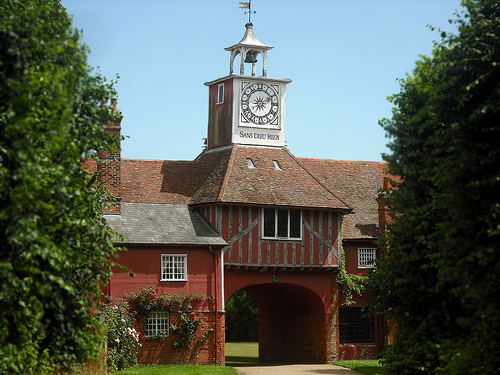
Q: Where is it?
A: This is at the church.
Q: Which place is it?
A: It is a church.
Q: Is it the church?
A: Yes, it is the church.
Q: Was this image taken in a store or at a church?
A: It was taken at a church.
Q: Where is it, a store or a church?
A: It is a church.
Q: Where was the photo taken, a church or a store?
A: It was taken at a church.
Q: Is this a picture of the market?
A: No, the picture is showing the church.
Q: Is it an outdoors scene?
A: Yes, it is outdoors.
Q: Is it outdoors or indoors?
A: It is outdoors.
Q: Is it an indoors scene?
A: No, it is outdoors.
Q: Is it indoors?
A: No, it is outdoors.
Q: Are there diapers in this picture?
A: No, there are no diapers.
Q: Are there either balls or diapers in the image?
A: No, there are no diapers or balls.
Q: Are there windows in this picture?
A: Yes, there is a window.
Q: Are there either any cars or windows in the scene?
A: Yes, there is a window.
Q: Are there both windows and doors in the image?
A: No, there is a window but no doors.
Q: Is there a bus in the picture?
A: No, there are no buses.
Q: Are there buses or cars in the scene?
A: No, there are no buses or cars.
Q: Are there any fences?
A: No, there are no fences.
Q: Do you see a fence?
A: No, there are no fences.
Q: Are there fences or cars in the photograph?
A: No, there are no fences or cars.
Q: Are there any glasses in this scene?
A: No, there are no glasses.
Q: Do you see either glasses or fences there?
A: No, there are no glasses or fences.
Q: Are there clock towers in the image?
A: Yes, there is a clock tower.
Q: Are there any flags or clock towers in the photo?
A: Yes, there is a clock tower.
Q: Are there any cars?
A: No, there are no cars.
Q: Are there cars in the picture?
A: No, there are no cars.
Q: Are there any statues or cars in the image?
A: No, there are no cars or statues.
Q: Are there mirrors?
A: No, there are no mirrors.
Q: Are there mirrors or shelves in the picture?
A: No, there are no mirrors or shelves.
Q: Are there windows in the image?
A: Yes, there is a window.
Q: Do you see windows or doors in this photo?
A: Yes, there is a window.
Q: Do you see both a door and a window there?
A: No, there is a window but no doors.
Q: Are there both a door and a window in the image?
A: No, there is a window but no doors.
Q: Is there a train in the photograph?
A: No, there are no trains.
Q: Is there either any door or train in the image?
A: No, there are no trains or doors.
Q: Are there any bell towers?
A: Yes, there is a bell tower.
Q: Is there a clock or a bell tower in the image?
A: Yes, there is a bell tower.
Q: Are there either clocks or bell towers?
A: Yes, there is a bell tower.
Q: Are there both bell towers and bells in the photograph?
A: Yes, there are both a bell tower and a bell.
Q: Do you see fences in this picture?
A: No, there are no fences.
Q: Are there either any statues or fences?
A: No, there are no fences or statues.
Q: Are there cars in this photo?
A: No, there are no cars.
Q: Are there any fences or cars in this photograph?
A: No, there are no cars or fences.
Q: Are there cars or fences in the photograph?
A: No, there are no cars or fences.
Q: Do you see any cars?
A: No, there are no cars.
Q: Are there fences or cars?
A: No, there are no cars or fences.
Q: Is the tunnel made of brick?
A: Yes, the tunnel is made of brick.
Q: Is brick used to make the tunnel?
A: Yes, the tunnel is made of brick.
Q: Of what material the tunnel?
A: The tunnel is made of brick.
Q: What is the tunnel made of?
A: The tunnel is made of brick.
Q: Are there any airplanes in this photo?
A: No, there are no airplanes.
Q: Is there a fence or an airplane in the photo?
A: No, there are no airplanes or fences.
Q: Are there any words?
A: Yes, there are words.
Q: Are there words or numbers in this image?
A: Yes, there are words.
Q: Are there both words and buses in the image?
A: No, there are words but no buses.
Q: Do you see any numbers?
A: No, there are no numbers.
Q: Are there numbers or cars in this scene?
A: No, there are no numbers or cars.